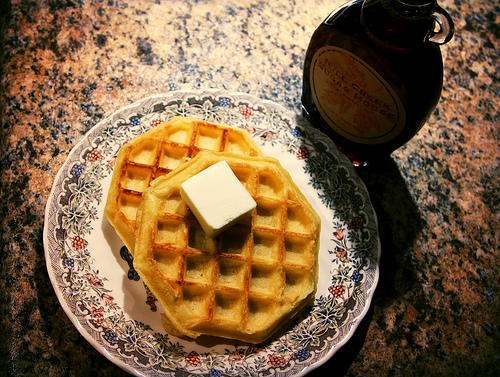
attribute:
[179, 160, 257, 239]
butter — square, large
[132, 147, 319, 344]
waffle — small, octagon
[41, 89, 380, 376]
plate — round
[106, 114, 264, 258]
waffle — small, octagon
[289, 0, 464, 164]
bottle — of maple syrup, maple syrup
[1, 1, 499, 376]
surface — marble, dark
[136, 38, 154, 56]
spot — black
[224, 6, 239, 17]
spot — black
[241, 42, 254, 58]
spot — black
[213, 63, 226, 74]
spot — black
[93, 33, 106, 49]
spot — black